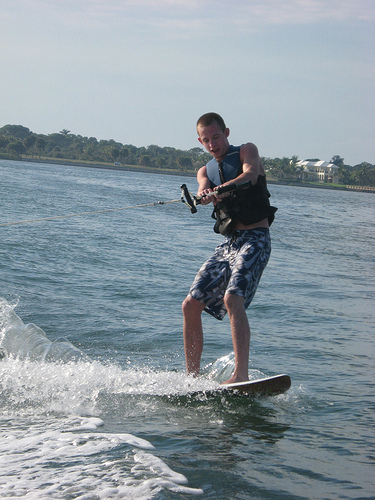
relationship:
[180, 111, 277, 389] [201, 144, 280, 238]
boy wearing a vest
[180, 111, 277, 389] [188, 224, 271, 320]
boy wearing short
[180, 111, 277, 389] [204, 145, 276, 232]
boy wearing vest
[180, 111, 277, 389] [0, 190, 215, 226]
boy holding onto a rope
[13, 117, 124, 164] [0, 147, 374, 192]
dense trees on shore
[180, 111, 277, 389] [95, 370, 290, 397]
boy riding board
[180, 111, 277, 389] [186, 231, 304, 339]
boy wearing shorts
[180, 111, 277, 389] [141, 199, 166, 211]
boy holding chord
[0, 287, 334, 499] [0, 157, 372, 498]
foam on water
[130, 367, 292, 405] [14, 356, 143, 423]
board causing wave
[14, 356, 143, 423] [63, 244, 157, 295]
wave in water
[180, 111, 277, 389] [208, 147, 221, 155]
boy has mouth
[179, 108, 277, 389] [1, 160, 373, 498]
boy wakeboarding on lake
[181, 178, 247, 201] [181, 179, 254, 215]
grip on grip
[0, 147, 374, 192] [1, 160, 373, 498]
shore near lake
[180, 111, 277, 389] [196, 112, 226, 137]
boy has hair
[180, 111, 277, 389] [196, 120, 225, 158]
boy has face